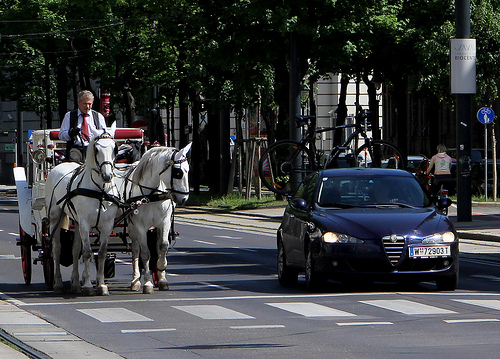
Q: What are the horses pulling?
A: Carriage.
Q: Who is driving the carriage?
A: A man.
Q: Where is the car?
A: On the road.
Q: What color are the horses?
A: White.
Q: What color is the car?
A: Black.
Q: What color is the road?
A: Gray.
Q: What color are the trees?
A: Green.